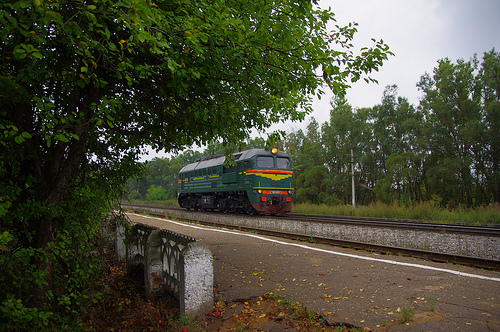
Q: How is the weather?
A: It is cloudy.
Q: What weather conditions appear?
A: It is cloudy.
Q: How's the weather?
A: It is cloudy.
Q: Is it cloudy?
A: Yes, it is cloudy.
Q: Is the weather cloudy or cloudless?
A: It is cloudy.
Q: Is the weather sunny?
A: No, it is cloudy.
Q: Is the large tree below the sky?
A: Yes, the tree is below the sky.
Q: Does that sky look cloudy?
A: Yes, the sky is cloudy.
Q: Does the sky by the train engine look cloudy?
A: Yes, the sky is cloudy.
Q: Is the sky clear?
A: No, the sky is cloudy.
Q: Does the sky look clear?
A: No, the sky is cloudy.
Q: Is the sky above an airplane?
A: No, the sky is above a locomotive.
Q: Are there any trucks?
A: No, there are no trucks.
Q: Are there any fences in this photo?
A: Yes, there is a fence.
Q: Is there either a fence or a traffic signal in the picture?
A: Yes, there is a fence.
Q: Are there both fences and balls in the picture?
A: No, there is a fence but no balls.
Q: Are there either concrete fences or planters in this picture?
A: Yes, there is a concrete fence.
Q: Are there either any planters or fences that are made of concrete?
A: Yes, the fence is made of concrete.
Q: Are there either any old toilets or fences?
A: Yes, there is an old fence.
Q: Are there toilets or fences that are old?
A: Yes, the fence is old.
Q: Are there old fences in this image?
A: Yes, there is an old fence.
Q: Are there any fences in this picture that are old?
A: Yes, there is a fence that is old.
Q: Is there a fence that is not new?
A: Yes, there is a old fence.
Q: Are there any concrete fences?
A: Yes, there is a fence that is made of concrete.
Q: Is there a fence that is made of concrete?
A: Yes, there is a fence that is made of concrete.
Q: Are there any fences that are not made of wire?
A: Yes, there is a fence that is made of concrete.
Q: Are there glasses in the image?
A: No, there are no glasses.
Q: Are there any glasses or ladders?
A: No, there are no glasses or ladders.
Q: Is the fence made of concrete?
A: Yes, the fence is made of concrete.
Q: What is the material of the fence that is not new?
A: The fence is made of cement.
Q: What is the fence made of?
A: The fence is made of concrete.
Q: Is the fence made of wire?
A: No, the fence is made of concrete.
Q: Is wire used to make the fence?
A: No, the fence is made of concrete.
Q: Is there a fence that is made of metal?
A: No, there is a fence but it is made of cement.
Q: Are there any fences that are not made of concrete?
A: No, there is a fence but it is made of concrete.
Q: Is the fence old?
A: Yes, the fence is old.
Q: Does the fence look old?
A: Yes, the fence is old.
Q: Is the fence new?
A: No, the fence is old.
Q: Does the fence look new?
A: No, the fence is old.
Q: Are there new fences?
A: No, there is a fence but it is old.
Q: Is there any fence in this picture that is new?
A: No, there is a fence but it is old.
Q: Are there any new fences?
A: No, there is a fence but it is old.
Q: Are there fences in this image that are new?
A: No, there is a fence but it is old.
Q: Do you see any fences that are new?
A: No, there is a fence but it is old.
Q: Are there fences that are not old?
A: No, there is a fence but it is old.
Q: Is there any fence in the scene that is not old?
A: No, there is a fence but it is old.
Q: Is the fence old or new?
A: The fence is old.